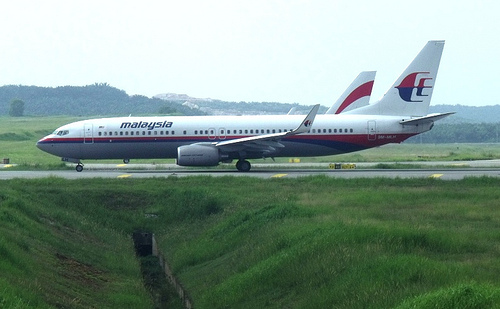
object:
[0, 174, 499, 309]
grass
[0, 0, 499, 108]
sky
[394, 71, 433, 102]
logo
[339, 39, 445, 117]
tail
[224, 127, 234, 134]
window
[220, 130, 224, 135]
window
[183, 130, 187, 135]
window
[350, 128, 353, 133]
window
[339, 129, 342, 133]
window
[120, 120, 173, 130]
logo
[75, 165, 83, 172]
landing gear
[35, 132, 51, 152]
nose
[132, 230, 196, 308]
ditch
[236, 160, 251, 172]
landing gear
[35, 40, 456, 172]
aircraft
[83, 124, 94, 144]
door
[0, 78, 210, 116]
trees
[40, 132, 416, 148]
stripes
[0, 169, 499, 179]
runway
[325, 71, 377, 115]
tail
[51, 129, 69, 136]
cockpit glass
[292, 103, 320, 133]
wingtip